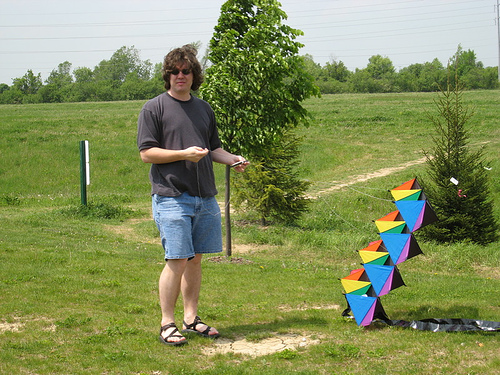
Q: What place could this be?
A: It is a field.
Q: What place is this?
A: It is a field.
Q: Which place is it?
A: It is a field.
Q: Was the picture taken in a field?
A: Yes, it was taken in a field.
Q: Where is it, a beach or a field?
A: It is a field.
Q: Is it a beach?
A: No, it is a field.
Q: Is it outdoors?
A: Yes, it is outdoors.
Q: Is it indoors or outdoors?
A: It is outdoors.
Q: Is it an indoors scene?
A: No, it is outdoors.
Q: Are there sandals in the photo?
A: Yes, there are sandals.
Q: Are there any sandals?
A: Yes, there are sandals.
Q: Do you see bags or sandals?
A: Yes, there are sandals.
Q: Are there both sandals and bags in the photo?
A: No, there are sandals but no bags.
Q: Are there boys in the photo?
A: No, there are no boys.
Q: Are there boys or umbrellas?
A: No, there are no boys or umbrellas.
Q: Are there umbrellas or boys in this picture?
A: No, there are no boys or umbrellas.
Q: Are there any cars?
A: No, there are no cars.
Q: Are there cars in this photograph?
A: No, there are no cars.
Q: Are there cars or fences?
A: No, there are no cars or fences.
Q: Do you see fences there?
A: No, there are no fences.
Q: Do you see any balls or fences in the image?
A: No, there are no fences or balls.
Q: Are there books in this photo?
A: No, there are no books.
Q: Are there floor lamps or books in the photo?
A: No, there are no books or floor lamps.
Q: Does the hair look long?
A: Yes, the hair is long.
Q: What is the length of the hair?
A: The hair is long.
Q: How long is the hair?
A: The hair is long.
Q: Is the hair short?
A: No, the hair is long.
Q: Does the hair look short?
A: No, the hair is long.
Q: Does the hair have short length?
A: No, the hair is long.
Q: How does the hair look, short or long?
A: The hair is long.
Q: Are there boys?
A: No, there are no boys.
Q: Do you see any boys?
A: No, there are no boys.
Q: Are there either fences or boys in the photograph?
A: No, there are no boys or fences.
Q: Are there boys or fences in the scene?
A: No, there are no boys or fences.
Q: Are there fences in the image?
A: No, there are no fences.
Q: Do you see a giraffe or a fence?
A: No, there are no fences or giraffes.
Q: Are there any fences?
A: No, there are no fences.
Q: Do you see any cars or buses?
A: No, there are no cars or buses.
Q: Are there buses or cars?
A: No, there are no cars or buses.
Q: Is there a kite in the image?
A: Yes, there is a kite.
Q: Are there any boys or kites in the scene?
A: Yes, there is a kite.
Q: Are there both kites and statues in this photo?
A: No, there is a kite but no statues.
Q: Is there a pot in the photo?
A: No, there are no pots.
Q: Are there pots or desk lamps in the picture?
A: No, there are no pots or desk lamps.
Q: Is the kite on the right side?
A: Yes, the kite is on the right of the image.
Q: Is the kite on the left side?
A: No, the kite is on the right of the image.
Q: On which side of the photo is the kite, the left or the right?
A: The kite is on the right of the image.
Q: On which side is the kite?
A: The kite is on the right of the image.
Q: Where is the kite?
A: The kite is on the ground.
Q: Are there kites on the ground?
A: Yes, there is a kite on the ground.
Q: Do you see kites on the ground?
A: Yes, there is a kite on the ground.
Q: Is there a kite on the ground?
A: Yes, there is a kite on the ground.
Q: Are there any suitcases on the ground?
A: No, there is a kite on the ground.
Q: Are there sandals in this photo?
A: Yes, there are sandals.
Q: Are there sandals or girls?
A: Yes, there are sandals.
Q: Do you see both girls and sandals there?
A: No, there are sandals but no girls.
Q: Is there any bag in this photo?
A: No, there are no bags.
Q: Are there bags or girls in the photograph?
A: No, there are no bags or girls.